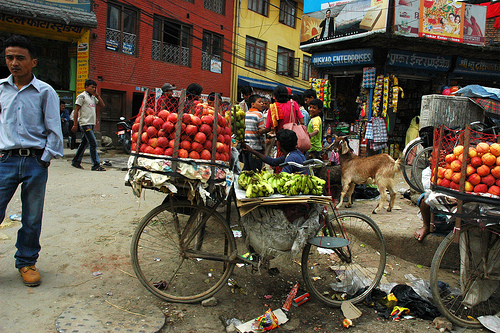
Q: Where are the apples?
A: In a cage.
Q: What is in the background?
A: Buildings.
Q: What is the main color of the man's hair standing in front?
A: Black.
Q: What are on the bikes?
A: Baskets.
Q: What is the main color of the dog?
A: Brown.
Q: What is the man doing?
A: HAnds in his pockets.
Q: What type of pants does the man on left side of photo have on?
A: Blue jeans.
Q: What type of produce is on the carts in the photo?
A: Fruits and vegetables.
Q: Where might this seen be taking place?
A: In remote village.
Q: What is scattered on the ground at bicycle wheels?
A: Trash.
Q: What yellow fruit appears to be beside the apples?
A: Bananas.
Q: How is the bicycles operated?
A: By peddeling.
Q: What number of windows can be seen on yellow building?
A: 5.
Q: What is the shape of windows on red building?
A: Square.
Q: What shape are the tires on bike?
A: Round.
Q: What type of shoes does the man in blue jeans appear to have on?
A: Work boots.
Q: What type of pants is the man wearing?
A: Blue jeans.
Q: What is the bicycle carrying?
A: Fruit.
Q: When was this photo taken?
A: In the daytime.